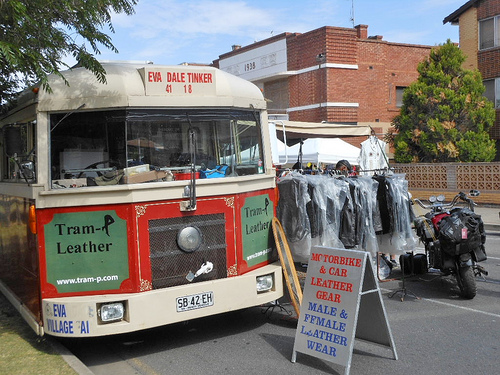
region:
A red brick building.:
[231, 35, 426, 136]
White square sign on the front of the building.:
[213, 48, 295, 77]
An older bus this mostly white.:
[1, 42, 281, 332]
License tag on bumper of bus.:
[171, 288, 225, 317]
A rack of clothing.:
[281, 160, 417, 270]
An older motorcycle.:
[410, 180, 498, 305]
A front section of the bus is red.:
[34, 198, 288, 292]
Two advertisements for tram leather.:
[38, 197, 278, 290]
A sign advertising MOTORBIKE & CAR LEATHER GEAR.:
[300, 240, 367, 303]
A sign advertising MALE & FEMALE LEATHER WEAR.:
[296, 293, 364, 367]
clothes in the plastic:
[276, 165, 317, 261]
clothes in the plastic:
[293, 175, 354, 262]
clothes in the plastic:
[334, 175, 363, 265]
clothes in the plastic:
[351, 183, 387, 278]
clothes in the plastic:
[382, 175, 418, 242]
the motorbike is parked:
[387, 151, 493, 334]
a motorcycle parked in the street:
[415, 195, 487, 298]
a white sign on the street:
[284, 243, 399, 362]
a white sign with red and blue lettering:
[303, 245, 368, 365]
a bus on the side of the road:
[15, 72, 265, 347]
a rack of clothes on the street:
[272, 167, 416, 250]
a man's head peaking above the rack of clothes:
[331, 161, 353, 172]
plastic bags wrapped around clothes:
[282, 179, 311, 249]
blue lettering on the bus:
[45, 302, 92, 335]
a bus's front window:
[51, 116, 262, 173]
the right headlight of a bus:
[100, 303, 126, 321]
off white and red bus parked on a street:
[0, 57, 288, 344]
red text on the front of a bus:
[142, 68, 214, 95]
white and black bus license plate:
[171, 293, 221, 311]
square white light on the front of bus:
[92, 298, 130, 322]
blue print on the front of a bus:
[37, 300, 94, 334]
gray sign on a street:
[288, 244, 400, 374]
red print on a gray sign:
[305, 250, 365, 304]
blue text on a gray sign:
[298, 298, 355, 365]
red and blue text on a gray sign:
[287, 243, 402, 373]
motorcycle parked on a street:
[407, 187, 492, 301]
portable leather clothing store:
[0, 58, 285, 336]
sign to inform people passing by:
[288, 247, 402, 372]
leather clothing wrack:
[276, 164, 408, 259]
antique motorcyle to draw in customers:
[398, 195, 489, 297]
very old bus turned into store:
[0, 61, 284, 336]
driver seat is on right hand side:
[56, 108, 130, 192]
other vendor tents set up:
[269, 118, 386, 173]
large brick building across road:
[213, 26, 444, 160]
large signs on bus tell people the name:
[46, 194, 271, 294]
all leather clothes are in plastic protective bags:
[279, 163, 411, 258]